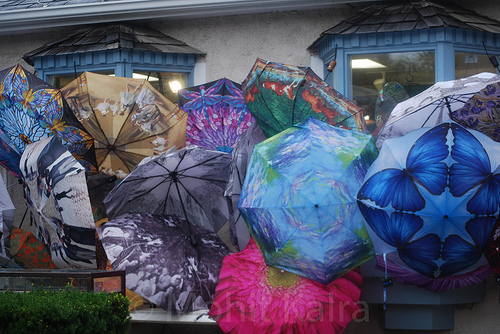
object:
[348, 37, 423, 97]
window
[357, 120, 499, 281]
umbrella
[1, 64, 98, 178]
umbrella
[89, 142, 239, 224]
umbrella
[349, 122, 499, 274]
blue umbrella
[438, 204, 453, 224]
black dot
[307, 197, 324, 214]
black dot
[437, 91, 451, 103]
black dot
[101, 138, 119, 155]
black dot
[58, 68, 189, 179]
umbrella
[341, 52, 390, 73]
light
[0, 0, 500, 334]
building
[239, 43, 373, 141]
umbrella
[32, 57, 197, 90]
paint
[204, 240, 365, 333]
umbrella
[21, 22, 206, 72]
top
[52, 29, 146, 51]
painted black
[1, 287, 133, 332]
bush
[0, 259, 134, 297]
glass case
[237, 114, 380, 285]
umbrella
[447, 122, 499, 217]
butterlfy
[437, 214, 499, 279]
butterlfy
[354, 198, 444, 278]
butterlfy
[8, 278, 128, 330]
grass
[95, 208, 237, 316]
umbrella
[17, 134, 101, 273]
umbrella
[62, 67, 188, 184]
brownumbrella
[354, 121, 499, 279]
motifs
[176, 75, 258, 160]
umbrella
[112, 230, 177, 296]
image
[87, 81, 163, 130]
humans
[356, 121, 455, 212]
butterfly